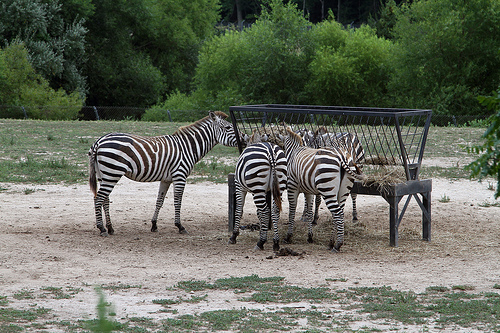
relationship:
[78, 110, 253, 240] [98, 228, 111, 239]
zebra has hoof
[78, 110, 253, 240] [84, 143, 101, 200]
zebra has tail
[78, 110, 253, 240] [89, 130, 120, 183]
zebra has behind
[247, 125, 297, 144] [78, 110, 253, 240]
hay for zebra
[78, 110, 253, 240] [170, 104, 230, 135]
zebra has mane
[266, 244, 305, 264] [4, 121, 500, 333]
feces on ground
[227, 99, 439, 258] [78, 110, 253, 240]
trough for feeding zebra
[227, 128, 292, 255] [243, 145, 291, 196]
zebra has butt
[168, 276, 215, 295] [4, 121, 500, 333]
grass growing on ground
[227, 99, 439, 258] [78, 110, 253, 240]
trough for zebra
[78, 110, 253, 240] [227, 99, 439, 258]
zebra behind trough